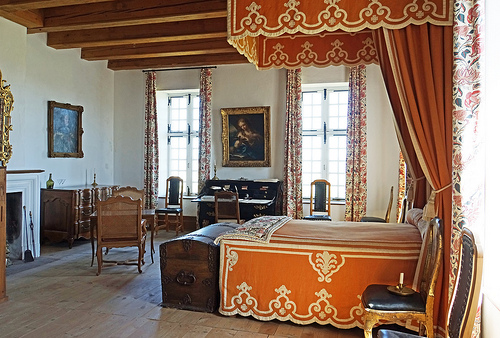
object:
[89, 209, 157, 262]
small table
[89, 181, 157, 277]
2 chairs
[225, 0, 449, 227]
orange canope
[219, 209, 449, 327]
bed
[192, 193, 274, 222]
wooden desk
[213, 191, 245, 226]
chair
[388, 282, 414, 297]
holder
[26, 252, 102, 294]
floors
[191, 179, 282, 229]
desk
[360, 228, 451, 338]
chair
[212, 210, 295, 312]
trunk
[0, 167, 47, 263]
fireplace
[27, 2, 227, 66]
ceiling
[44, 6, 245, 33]
beam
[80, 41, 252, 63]
beam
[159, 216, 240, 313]
trunk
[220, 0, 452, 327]
bed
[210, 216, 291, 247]
blanket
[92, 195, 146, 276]
chair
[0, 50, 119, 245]
wall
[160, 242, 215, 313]
brown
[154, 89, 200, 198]
windows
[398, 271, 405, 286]
candle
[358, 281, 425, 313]
seat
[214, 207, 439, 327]
bedspread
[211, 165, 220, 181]
candlestick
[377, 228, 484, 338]
chair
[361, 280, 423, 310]
cushion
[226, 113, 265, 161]
painting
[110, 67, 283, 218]
wall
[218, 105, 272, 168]
frame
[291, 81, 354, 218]
window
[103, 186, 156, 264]
chairs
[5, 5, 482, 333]
bedroom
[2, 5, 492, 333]
room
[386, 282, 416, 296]
candlestick